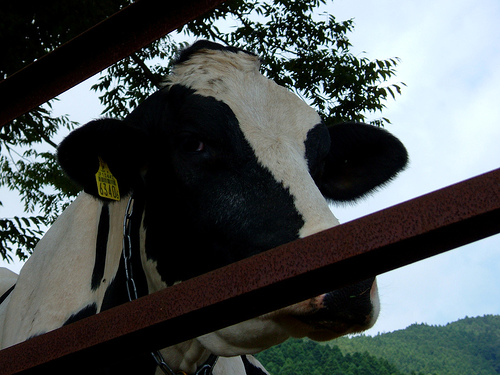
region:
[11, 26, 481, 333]
The cow is on a farm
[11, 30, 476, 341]
The cow is owned by a farmer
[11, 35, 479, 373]
The cow is part of someone's stock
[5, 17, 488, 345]
The cow is a female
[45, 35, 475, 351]
The cow is behind the fence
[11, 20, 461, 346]
The cow has a tag in its ear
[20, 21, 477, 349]
The cow is out in the sunshine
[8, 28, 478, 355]
The cow is enjoying her day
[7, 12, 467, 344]
The cow is very contented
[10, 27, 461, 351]
The cow was waiting to be fed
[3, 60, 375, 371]
The cow is in a fence.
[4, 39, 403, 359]
The cow is black and white.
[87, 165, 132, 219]
The tag is yellow.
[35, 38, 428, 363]
The cow has a tag in his ear.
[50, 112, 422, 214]
his ears are black.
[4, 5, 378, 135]
The tree is leafy.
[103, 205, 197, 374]
He has a chain.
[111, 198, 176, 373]
The chain is silver.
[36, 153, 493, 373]
The fence is maroon.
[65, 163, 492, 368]
The fence is metal.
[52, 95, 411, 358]
black and white cow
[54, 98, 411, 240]
cow has black ears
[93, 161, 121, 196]
yellow tag in ear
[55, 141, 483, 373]
brown rail in front of cow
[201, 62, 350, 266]
white stripe on cow's face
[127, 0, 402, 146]
green and leafy tree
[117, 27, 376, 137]
green tree behind cow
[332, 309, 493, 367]
many trees on hill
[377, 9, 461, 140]
sky is blue and white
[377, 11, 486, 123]
thick clouds in sky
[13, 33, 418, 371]
a cow behind a fence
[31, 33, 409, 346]
the head of a cow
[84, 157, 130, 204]
a yellow tag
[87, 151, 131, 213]
a tag in a cow's ear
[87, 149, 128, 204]
a yellow tag in a cow's ear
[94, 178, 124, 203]
a yellow tag says 6340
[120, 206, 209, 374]
a chain on a cow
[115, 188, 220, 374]
a chain on a cow's neck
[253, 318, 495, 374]
trees in the distance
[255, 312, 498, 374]
tree covered hill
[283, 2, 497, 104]
green leaves and blue sky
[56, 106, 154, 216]
yellow tag in a cow's ear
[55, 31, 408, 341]
black and white cow's head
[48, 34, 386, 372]
cow with chain around neck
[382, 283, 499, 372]
tree covered mountain top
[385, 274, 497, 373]
mountain top and blue sky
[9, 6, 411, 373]
cow behind wooden fence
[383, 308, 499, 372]
green foliage on a mountain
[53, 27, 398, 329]
cow with a white stripe on nose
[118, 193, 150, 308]
links of a silver chain